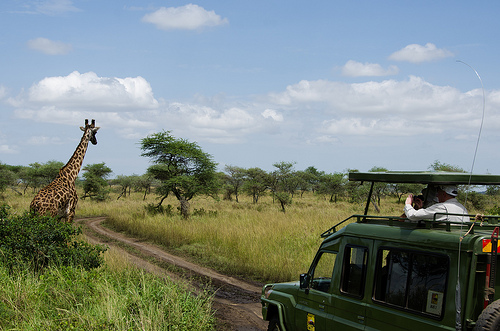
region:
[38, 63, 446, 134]
clouds in the sky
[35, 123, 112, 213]
a giraffe standing in a field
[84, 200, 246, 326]
a dirt road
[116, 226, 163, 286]
tracks in the dirt road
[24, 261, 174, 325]
tall grass next to the road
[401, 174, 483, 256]
a man standing in a jeep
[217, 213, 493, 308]
a green jeep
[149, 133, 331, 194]
trees in the grass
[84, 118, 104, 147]
the head of the giraffe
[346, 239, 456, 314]
windows in the truck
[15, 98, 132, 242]
giraffe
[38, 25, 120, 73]
white clouds in blue sky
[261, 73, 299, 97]
white clouds in blue sky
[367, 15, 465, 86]
white clouds in blue sky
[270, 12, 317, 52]
white clouds in blue sky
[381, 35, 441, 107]
white clouds in blue sky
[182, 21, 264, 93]
white clouds in blue sky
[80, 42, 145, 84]
white clouds in blue sky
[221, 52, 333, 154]
white clouds in blue sky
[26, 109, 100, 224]
a giraffe in wild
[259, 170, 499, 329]
a green vehicle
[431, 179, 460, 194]
a white hat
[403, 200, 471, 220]
a white shirt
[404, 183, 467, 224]
a man watching animal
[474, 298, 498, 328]
a tire on back of truck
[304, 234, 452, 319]
the side windows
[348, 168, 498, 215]
canopy on top of truck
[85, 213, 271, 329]
pathway through wilderness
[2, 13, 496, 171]
clouds in the sky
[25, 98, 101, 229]
giraffe on the roadside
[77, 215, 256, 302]
road in the savannah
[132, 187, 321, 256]
grasses on the plain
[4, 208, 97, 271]
bushes on the plain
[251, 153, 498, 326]
truck coming down the road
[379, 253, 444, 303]
windows on the truck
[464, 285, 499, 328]
tire on back of truck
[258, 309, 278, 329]
front tire on vehicle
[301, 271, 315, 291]
mirror on the truck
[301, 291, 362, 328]
doors on the truck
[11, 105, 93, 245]
a large adult giraffe walking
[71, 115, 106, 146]
the head of an adult giraffe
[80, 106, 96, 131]
the horns of an adult giraffe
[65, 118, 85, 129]
the head of an adult giraffe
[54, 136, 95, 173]
the neck of an adult giraffe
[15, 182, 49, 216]
the rear end of an adult giraffe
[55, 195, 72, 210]
the spots of an adult giraffe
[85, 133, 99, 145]
the nose of an adult giraffe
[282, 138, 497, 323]
a guy looking at a giraffe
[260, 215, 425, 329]
a jungle safari jeep